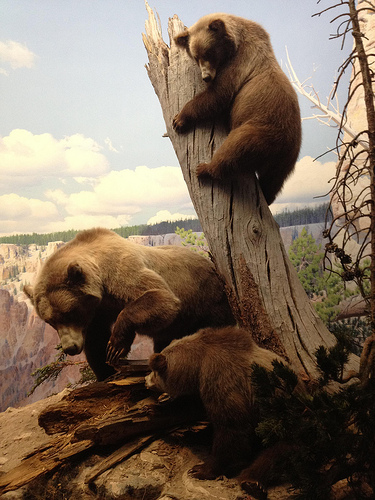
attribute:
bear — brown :
[136, 323, 310, 483]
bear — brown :
[170, 12, 302, 206]